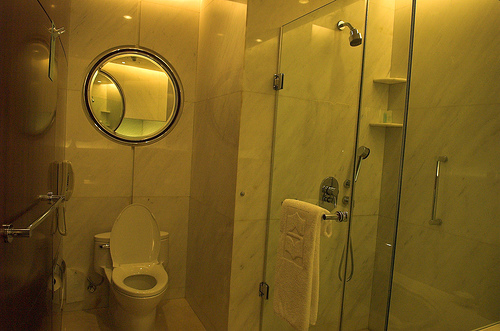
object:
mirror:
[87, 51, 180, 141]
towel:
[274, 199, 334, 330]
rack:
[281, 197, 347, 222]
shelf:
[371, 76, 407, 85]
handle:
[99, 243, 110, 249]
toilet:
[94, 202, 172, 330]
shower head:
[336, 20, 362, 47]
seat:
[111, 262, 170, 297]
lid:
[109, 203, 161, 267]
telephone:
[56, 159, 76, 236]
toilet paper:
[53, 274, 61, 291]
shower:
[259, 0, 499, 331]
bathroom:
[2, 1, 498, 328]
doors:
[257, 0, 415, 330]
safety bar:
[429, 156, 448, 226]